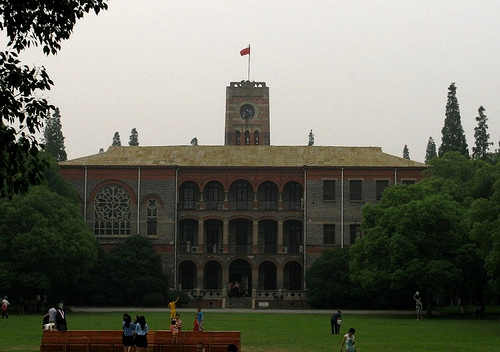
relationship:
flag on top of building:
[239, 45, 253, 80] [55, 81, 428, 308]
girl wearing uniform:
[133, 316, 148, 352] [135, 324, 148, 347]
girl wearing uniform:
[122, 317, 132, 349] [124, 321, 135, 346]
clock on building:
[241, 101, 257, 121] [55, 81, 428, 308]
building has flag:
[55, 81, 428, 308] [239, 45, 253, 80]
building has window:
[55, 81, 428, 308] [322, 177, 338, 200]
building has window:
[55, 81, 428, 308] [348, 178, 363, 204]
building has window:
[55, 81, 428, 308] [374, 177, 389, 204]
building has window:
[55, 81, 428, 308] [322, 221, 336, 247]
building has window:
[55, 81, 428, 308] [349, 221, 363, 247]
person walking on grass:
[338, 326, 360, 351] [0, 312, 498, 352]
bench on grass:
[37, 330, 243, 352] [0, 312, 498, 352]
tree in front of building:
[344, 179, 470, 317] [55, 81, 428, 308]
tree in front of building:
[99, 236, 167, 305] [55, 81, 428, 308]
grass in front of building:
[0, 312, 498, 352] [55, 81, 428, 308]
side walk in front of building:
[62, 303, 444, 314] [55, 81, 428, 308]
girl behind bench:
[133, 316, 148, 352] [37, 330, 243, 352]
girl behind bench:
[122, 317, 132, 349] [37, 330, 243, 352]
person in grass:
[338, 326, 360, 351] [0, 312, 498, 352]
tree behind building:
[442, 81, 469, 157] [55, 81, 428, 308]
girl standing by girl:
[133, 316, 148, 352] [122, 317, 132, 349]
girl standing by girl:
[122, 317, 132, 349] [133, 316, 148, 352]